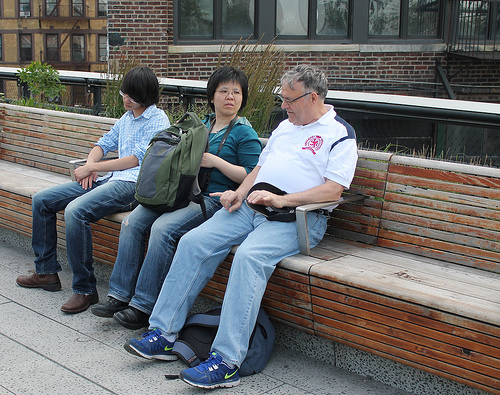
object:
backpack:
[132, 112, 208, 214]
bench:
[0, 103, 500, 393]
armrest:
[70, 160, 96, 189]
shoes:
[177, 350, 240, 389]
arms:
[87, 117, 170, 172]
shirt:
[252, 105, 358, 218]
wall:
[104, 0, 500, 162]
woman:
[88, 65, 263, 331]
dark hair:
[205, 65, 249, 110]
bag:
[160, 307, 277, 381]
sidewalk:
[0, 248, 500, 395]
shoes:
[56, 283, 100, 316]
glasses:
[274, 87, 312, 106]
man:
[122, 63, 358, 389]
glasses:
[213, 86, 244, 97]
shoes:
[112, 302, 149, 331]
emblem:
[298, 133, 324, 155]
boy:
[13, 66, 173, 313]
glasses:
[118, 89, 143, 106]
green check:
[221, 369, 239, 380]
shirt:
[93, 103, 169, 184]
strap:
[212, 115, 237, 156]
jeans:
[146, 196, 328, 368]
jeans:
[106, 194, 220, 316]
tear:
[120, 218, 132, 230]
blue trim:
[331, 114, 357, 142]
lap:
[143, 215, 183, 246]